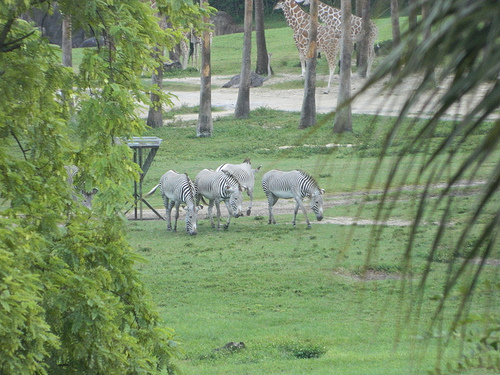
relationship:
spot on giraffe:
[319, 32, 324, 45] [281, 2, 362, 94]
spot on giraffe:
[330, 30, 336, 37] [281, 2, 362, 94]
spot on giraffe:
[323, 30, 331, 40] [281, 2, 362, 94]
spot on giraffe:
[292, 5, 302, 13] [281, 2, 362, 94]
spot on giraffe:
[301, 28, 309, 38] [281, 2, 362, 94]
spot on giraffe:
[354, 16, 362, 27] [303, 0, 379, 86]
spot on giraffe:
[352, 14, 355, 24] [303, 0, 379, 86]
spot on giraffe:
[331, 8, 341, 13] [303, 0, 379, 86]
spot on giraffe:
[327, 27, 333, 30] [303, 0, 379, 86]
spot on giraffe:
[327, 6, 333, 14] [303, 0, 379, 86]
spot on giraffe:
[293, 8, 306, 18] [281, 0, 350, 98]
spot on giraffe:
[295, 14, 305, 24] [281, 0, 350, 98]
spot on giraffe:
[317, 33, 327, 43] [281, 0, 350, 98]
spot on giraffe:
[327, 27, 338, 38] [281, 0, 350, 98]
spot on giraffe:
[327, 47, 333, 57] [281, 0, 350, 98]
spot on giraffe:
[327, 5, 332, 13] [300, 3, 382, 93]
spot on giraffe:
[333, 5, 341, 15] [300, 3, 382, 93]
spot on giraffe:
[316, 11, 324, 16] [300, 3, 382, 93]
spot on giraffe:
[347, 13, 355, 22] [300, 3, 382, 93]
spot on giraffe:
[328, 19, 338, 28] [300, 3, 382, 93]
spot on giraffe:
[316, 6, 325, 14] [301, 0, 380, 98]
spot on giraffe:
[320, 10, 330, 19] [301, 0, 380, 98]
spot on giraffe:
[325, 8, 335, 16] [301, 0, 380, 98]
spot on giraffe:
[333, 6, 339, 14] [301, 0, 380, 98]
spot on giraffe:
[357, 16, 362, 29] [301, 0, 380, 98]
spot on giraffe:
[298, 23, 310, 45] [269, 0, 378, 92]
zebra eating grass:
[208, 163, 257, 226] [200, 216, 399, 349]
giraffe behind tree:
[273, 0, 305, 75] [332, 8, 358, 141]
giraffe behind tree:
[282, 0, 343, 93] [332, 8, 358, 141]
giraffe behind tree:
[273, 0, 305, 75] [297, 0, 317, 130]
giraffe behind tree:
[282, 0, 343, 93] [297, 0, 317, 130]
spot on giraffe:
[289, 9, 298, 24] [281, 0, 350, 98]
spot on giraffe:
[320, 9, 328, 22] [282, 0, 343, 94]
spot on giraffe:
[297, 38, 306, 47] [282, 0, 343, 93]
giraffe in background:
[313, 0, 368, 100] [140, 1, 466, 131]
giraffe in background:
[273, 0, 306, 77] [140, 1, 466, 131]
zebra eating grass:
[155, 166, 205, 237] [160, 234, 225, 249]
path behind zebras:
[81, 179, 477, 220] [137, 157, 329, 236]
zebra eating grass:
[155, 166, 205, 237] [115, 109, 496, 373]